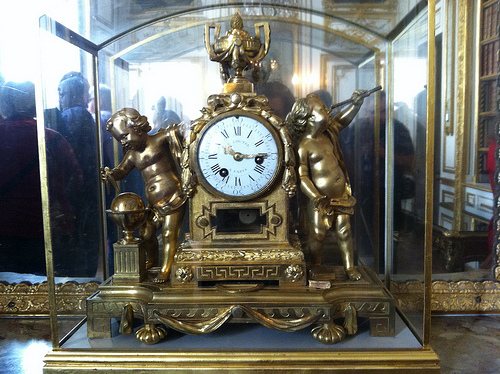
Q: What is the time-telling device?
A: A clock.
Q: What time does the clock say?
A: 10:15.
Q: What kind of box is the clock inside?
A: Glass.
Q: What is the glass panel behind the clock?
A: A mirror.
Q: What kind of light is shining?
A: Sunlight.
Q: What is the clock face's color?
A: White.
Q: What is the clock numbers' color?
A: Black.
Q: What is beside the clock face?
A: Statues of children.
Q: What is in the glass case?
A: A clock with statues.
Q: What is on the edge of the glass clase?
A: Gold frame.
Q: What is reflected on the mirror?
A: People standing.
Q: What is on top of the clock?
A: A statue.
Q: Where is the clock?
A: In the glass box.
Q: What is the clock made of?
A: Gold.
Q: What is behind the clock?
A: A mirror.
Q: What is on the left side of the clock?
A: A statue.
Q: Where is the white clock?
A: On the statue.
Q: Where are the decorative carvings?
A: On the bottom of the clock stand.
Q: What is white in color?
A: The clock face.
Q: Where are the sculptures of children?
A: Beside the clock.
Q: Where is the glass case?
A: On a wooden table.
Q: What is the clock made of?
A: Bronze.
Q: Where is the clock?
A: In a museum.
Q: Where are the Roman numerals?
A: On the clock face.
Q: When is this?
A: Daytime.